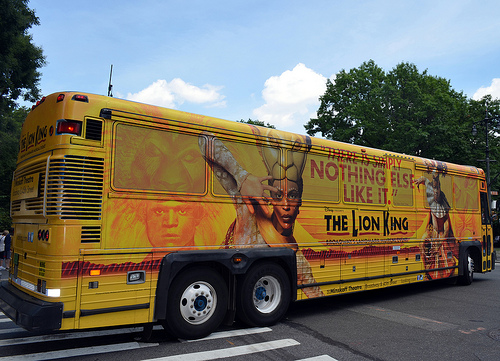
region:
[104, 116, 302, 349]
A bus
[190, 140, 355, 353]
A bus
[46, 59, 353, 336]
A bus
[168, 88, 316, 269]
A bus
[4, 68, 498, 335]
a yellow bus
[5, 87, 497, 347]
the bus is large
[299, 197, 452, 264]
the bus says The Lion King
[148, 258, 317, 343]
the rims are white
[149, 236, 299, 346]
the tires are black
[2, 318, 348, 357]
white lines on the street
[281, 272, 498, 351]
the street is gray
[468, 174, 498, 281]
the bus has doors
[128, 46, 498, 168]
clouds in the sky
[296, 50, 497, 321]
trees by the bus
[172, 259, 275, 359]
Black tire on bus.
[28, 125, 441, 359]
Bus is mostly yellow in color.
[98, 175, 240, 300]
Face on the side of the bus.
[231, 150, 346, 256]
Human face on the side of the bus.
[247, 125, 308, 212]
Animal face on the side of the bus.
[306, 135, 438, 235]
Red writing on the side of the bus.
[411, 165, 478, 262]
Animal on the side of the bus.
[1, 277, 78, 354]
Black bumper on the back of the bus.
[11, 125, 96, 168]
Black writing on the back of bus.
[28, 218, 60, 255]
Lights on the back of bus.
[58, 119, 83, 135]
rear red bus light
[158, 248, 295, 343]
two bus wheels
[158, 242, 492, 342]
three bus wheels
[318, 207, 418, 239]
Black print reading The Lion King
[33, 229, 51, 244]
three red round bus lights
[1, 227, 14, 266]
person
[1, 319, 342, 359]
white lines on a street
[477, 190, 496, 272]
double bus doors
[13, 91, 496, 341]
yellow bus covered with a Lion King Advertisement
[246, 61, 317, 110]
white cloud in a blue sky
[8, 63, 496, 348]
yellow passenger bus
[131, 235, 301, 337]
two large truck wheels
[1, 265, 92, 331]
black bumper on the back of the yellow bus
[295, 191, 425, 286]
Big yellow bus with the letter T on it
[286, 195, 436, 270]
Big yellow bus with the letter h on it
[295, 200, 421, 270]
Big yellow bus with the letter e on it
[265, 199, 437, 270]
Big yellow bus with the letter l on it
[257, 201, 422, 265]
Big yellow bus with the letter i on it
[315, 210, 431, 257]
Big yellow bus with the letter o on it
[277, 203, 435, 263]
Big yellow bus with the letter n on it